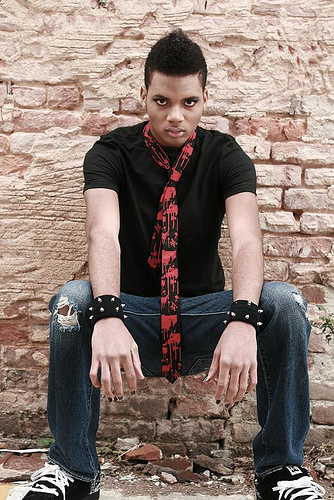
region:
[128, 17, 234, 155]
head of a person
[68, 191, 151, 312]
arm of a person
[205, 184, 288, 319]
arm of a person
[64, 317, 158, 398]
hand of a person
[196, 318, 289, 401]
hand of a person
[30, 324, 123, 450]
leg of a person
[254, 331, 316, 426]
leg of a person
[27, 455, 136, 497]
feet of a person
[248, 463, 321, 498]
feet of a person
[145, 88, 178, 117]
an eye of a person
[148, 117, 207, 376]
black and red tie on man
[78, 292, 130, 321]
black spiky wrist cuffs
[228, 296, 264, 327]
black spiky wrist covers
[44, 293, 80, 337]
rip in hole of jeans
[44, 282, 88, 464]
blue jeans on man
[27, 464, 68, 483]
white shoe laces on shoes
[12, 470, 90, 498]
black shoes on feet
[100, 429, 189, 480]
broken bricks on the ground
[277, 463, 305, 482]
logo on front of shoes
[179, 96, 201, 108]
black eye liner on face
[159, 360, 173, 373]
red spot on tie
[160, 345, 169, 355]
red spot on tie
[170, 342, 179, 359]
red spot on tie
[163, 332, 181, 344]
red spot on tie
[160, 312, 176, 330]
red spot on tie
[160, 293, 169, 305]
red spot on tie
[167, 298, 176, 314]
red spot on tie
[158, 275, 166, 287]
red spot on tie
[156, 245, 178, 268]
red spot on tie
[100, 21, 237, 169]
man has a Mohawk cut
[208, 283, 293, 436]
black fingernail polish on hand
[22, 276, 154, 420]
he has ripped jeans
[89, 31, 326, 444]
sitting in front of brick wall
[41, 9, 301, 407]
the man is black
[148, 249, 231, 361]
the tie is red and black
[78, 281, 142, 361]
wristbands have silver spikes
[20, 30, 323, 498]
man squatting against brick wall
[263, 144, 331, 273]
brick surface of wall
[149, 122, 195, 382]
black and red tie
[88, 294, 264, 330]
two wrist bands with studs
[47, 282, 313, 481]
blue jeans with holes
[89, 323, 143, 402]
fingers with black polish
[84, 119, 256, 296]
black short sleeved shirt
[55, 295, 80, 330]
hole in denim material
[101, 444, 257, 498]
broken bricks on ground